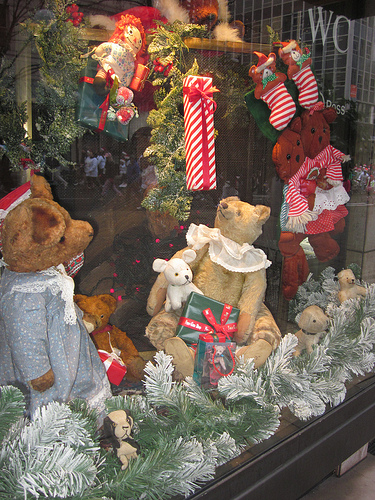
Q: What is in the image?
A: Teddy bear.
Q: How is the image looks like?
A: Good.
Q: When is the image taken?
A: Teddy bears in shop.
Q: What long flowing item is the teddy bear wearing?
A: Dress.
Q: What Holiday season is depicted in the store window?
A: Christmas.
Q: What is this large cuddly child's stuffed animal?
A: Teddy bear.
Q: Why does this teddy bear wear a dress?
A: It's a female.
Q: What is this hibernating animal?
A: Bear.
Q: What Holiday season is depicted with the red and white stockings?
A: Christmas.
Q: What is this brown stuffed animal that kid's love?
A: Teddy bear.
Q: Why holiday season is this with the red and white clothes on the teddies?
A: Christmas.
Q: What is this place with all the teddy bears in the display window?
A: Store.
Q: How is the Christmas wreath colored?
A: In green.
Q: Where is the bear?
A: In a window.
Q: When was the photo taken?
A: Christmas season.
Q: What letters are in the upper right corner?
A: WC.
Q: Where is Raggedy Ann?
A: Hanging on the tree.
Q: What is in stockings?
A: Teddy bears.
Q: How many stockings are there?
A: Two.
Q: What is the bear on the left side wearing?
A: Dress.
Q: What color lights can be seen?
A: Red.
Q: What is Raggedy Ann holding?
A: Present.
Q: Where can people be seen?
A: Reflection in window.